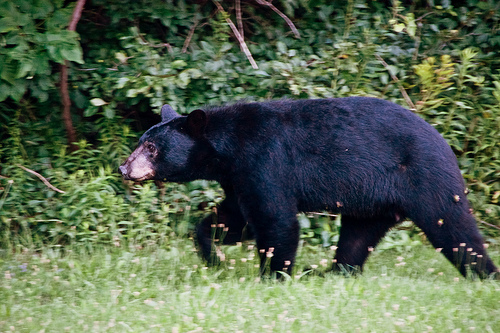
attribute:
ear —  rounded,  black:
[158, 101, 185, 125]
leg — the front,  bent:
[194, 193, 243, 271]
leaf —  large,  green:
[57, 36, 85, 64]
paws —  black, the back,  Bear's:
[303, 267, 359, 278]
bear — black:
[119, 93, 496, 278]